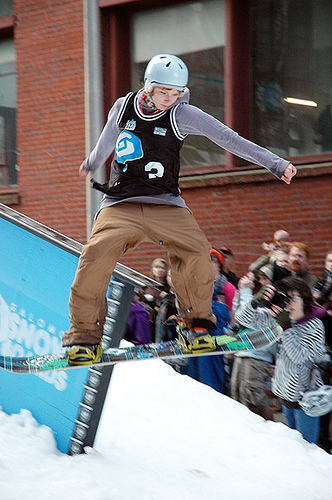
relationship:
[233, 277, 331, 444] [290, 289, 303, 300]
photographer wearing glasses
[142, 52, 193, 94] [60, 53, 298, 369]
helmet of rider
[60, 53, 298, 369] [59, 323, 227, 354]
rider wearing snow boots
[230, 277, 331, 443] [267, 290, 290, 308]
photographer has camera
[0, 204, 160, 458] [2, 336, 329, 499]
wall in snow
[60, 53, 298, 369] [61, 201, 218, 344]
rider wearing pants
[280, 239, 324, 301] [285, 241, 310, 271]
man with red hair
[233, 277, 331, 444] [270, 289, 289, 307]
photographer using camera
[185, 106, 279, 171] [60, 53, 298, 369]
arm of rider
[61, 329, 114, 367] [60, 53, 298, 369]
boot of rider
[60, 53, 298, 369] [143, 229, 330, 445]
rider in crowd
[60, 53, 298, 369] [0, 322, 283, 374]
rider on snowboard